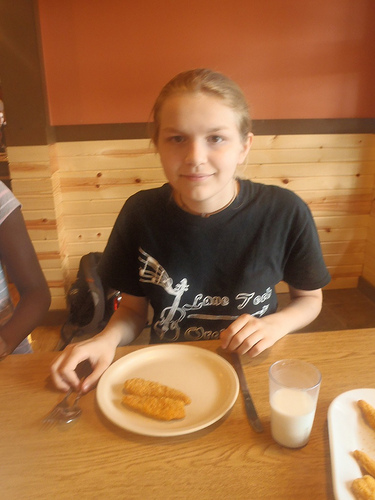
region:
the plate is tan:
[99, 340, 243, 447]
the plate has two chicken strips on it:
[117, 376, 190, 426]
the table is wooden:
[0, 320, 374, 497]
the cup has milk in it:
[268, 352, 320, 452]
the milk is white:
[267, 382, 319, 452]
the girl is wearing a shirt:
[101, 170, 333, 336]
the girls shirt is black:
[80, 167, 331, 352]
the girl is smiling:
[94, 174, 332, 352]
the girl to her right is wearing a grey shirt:
[0, 173, 35, 359]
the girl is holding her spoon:
[64, 371, 89, 423]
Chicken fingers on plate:
[118, 374, 195, 458]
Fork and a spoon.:
[50, 372, 86, 434]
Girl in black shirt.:
[118, 69, 297, 340]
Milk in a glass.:
[262, 352, 319, 481]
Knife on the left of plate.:
[214, 333, 265, 456]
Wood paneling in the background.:
[22, 113, 121, 260]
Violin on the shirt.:
[155, 255, 193, 335]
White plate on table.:
[109, 341, 215, 432]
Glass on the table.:
[249, 372, 315, 473]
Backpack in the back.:
[68, 246, 128, 348]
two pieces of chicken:
[122, 377, 190, 420]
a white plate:
[97, 342, 241, 437]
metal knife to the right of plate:
[230, 347, 265, 438]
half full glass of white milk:
[268, 357, 321, 448]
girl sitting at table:
[50, 80, 325, 390]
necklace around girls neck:
[178, 180, 240, 216]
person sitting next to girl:
[0, 181, 52, 361]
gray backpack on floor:
[57, 249, 111, 349]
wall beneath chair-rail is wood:
[6, 136, 374, 310]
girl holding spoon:
[59, 373, 91, 421]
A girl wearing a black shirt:
[49, 68, 331, 393]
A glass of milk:
[269, 357, 321, 449]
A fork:
[40, 359, 87, 423]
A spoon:
[63, 363, 92, 425]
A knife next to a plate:
[230, 347, 264, 433]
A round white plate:
[95, 342, 238, 437]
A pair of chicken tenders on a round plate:
[120, 376, 193, 420]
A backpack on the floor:
[60, 250, 123, 349]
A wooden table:
[0, 326, 374, 499]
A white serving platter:
[327, 386, 374, 498]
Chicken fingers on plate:
[122, 377, 191, 422]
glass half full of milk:
[266, 358, 323, 447]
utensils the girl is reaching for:
[42, 367, 84, 427]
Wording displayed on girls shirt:
[137, 246, 270, 348]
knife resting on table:
[231, 349, 263, 434]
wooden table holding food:
[2, 327, 373, 497]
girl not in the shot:
[0, 170, 56, 361]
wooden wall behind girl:
[5, 131, 370, 289]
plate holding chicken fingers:
[93, 343, 239, 438]